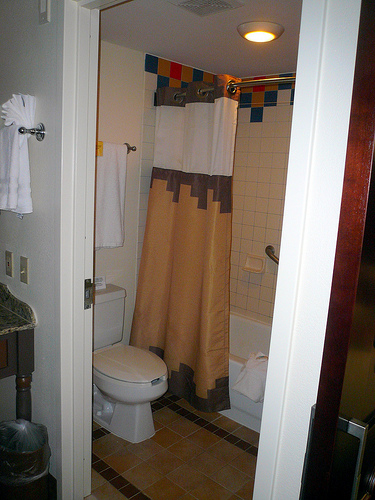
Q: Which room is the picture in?
A: It is at the bathroom.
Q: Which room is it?
A: It is a bathroom.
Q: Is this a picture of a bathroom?
A: Yes, it is showing a bathroom.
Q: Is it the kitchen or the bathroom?
A: It is the bathroom.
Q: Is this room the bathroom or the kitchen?
A: It is the bathroom.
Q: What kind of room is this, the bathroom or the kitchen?
A: It is the bathroom.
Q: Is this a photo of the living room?
A: No, the picture is showing the bathroom.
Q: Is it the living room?
A: No, it is the bathroom.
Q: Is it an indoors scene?
A: Yes, it is indoors.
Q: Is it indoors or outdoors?
A: It is indoors.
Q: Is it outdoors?
A: No, it is indoors.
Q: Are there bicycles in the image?
A: No, there are no bicycles.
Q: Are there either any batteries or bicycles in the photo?
A: No, there are no bicycles or batteries.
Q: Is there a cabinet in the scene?
A: No, there are no cabinets.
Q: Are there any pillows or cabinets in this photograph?
A: No, there are no cabinets or pillows.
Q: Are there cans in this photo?
A: Yes, there is a can.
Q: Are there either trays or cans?
A: Yes, there is a can.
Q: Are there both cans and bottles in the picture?
A: No, there is a can but no bottles.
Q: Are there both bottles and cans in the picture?
A: No, there is a can but no bottles.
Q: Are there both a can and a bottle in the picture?
A: No, there is a can but no bottles.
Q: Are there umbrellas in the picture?
A: No, there are no umbrellas.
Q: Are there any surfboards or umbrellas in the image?
A: No, there are no umbrellas or surfboards.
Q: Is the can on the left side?
A: Yes, the can is on the left of the image.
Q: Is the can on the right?
A: No, the can is on the left of the image.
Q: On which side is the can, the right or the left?
A: The can is on the left of the image.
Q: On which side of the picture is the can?
A: The can is on the left of the image.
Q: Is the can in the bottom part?
A: Yes, the can is in the bottom of the image.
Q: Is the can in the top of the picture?
A: No, the can is in the bottom of the image.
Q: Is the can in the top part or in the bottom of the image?
A: The can is in the bottom of the image.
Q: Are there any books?
A: No, there are no books.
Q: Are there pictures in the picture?
A: No, there are no pictures.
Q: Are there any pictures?
A: No, there are no pictures.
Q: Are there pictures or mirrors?
A: No, there are no pictures or mirrors.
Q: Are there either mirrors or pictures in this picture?
A: No, there are no pictures or mirrors.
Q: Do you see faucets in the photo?
A: No, there are no faucets.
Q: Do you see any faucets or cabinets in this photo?
A: No, there are no faucets or cabinets.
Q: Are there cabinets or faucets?
A: No, there are no faucets or cabinets.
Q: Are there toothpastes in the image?
A: No, there are no toothpastes.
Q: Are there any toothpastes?
A: No, there are no toothpastes.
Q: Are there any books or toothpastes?
A: No, there are no toothpastes or books.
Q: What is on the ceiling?
A: The light fixture is on the ceiling.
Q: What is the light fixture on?
A: The light fixture is on the ceiling.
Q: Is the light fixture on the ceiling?
A: Yes, the light fixture is on the ceiling.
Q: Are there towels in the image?
A: Yes, there is a towel.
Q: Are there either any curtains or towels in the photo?
A: Yes, there is a towel.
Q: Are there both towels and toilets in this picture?
A: Yes, there are both a towel and a toilet.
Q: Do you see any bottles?
A: No, there are no bottles.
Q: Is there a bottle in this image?
A: No, there are no bottles.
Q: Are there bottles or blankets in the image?
A: No, there are no bottles or blankets.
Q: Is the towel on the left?
A: Yes, the towel is on the left of the image.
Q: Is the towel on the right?
A: No, the towel is on the left of the image.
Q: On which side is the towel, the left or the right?
A: The towel is on the left of the image.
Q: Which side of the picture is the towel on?
A: The towel is on the left of the image.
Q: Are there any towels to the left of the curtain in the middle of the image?
A: Yes, there is a towel to the left of the curtain.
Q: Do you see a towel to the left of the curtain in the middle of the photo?
A: Yes, there is a towel to the left of the curtain.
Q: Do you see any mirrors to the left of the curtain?
A: No, there is a towel to the left of the curtain.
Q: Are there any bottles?
A: No, there are no bottles.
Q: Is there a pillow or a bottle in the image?
A: No, there are no bottles or pillows.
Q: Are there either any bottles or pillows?
A: No, there are no bottles or pillows.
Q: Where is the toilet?
A: The toilet is in the bathroom.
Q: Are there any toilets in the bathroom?
A: Yes, there is a toilet in the bathroom.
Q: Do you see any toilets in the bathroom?
A: Yes, there is a toilet in the bathroom.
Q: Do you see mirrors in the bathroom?
A: No, there is a toilet in the bathroom.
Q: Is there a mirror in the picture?
A: No, there are no mirrors.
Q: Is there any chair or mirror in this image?
A: No, there are no mirrors or chairs.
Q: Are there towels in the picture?
A: Yes, there is a towel.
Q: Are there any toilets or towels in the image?
A: Yes, there is a towel.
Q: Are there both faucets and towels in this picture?
A: No, there is a towel but no faucets.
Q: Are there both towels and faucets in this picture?
A: No, there is a towel but no faucets.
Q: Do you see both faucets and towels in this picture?
A: No, there is a towel but no faucets.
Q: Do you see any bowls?
A: No, there are no bowls.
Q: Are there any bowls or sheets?
A: No, there are no bowls or sheets.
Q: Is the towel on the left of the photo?
A: Yes, the towel is on the left of the image.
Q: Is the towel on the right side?
A: No, the towel is on the left of the image.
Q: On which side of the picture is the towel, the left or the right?
A: The towel is on the left of the image.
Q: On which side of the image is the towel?
A: The towel is on the left of the image.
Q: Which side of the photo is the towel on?
A: The towel is on the left of the image.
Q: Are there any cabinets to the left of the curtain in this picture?
A: No, there is a towel to the left of the curtain.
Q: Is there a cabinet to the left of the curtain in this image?
A: No, there is a towel to the left of the curtain.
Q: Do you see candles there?
A: No, there are no candles.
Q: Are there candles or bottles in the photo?
A: No, there are no candles or bottles.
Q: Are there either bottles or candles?
A: No, there are no candles or bottles.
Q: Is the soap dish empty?
A: Yes, the soap dish is empty.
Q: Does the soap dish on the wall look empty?
A: Yes, the soap dish is empty.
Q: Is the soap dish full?
A: No, the soap dish is empty.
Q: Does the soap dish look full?
A: No, the soap dish is empty.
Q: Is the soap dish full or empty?
A: The soap dish is empty.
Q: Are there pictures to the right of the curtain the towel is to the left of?
A: No, there is a soap dish to the right of the curtain.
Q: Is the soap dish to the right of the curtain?
A: Yes, the soap dish is to the right of the curtain.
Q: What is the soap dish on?
A: The soap dish is on the wall.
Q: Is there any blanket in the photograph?
A: No, there are no blankets.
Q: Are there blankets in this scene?
A: No, there are no blankets.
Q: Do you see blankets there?
A: No, there are no blankets.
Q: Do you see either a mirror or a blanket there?
A: No, there are no blankets or mirrors.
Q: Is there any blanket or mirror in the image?
A: No, there are no blankets or mirrors.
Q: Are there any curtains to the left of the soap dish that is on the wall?
A: Yes, there is a curtain to the left of the soap dish.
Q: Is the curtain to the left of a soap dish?
A: Yes, the curtain is to the left of a soap dish.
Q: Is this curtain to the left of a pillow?
A: No, the curtain is to the left of a soap dish.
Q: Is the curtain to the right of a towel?
A: Yes, the curtain is to the right of a towel.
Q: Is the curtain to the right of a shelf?
A: No, the curtain is to the right of a towel.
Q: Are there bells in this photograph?
A: No, there are no bells.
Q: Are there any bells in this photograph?
A: No, there are no bells.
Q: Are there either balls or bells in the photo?
A: No, there are no bells or balls.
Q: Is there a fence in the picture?
A: No, there are no fences.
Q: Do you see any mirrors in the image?
A: No, there are no mirrors.